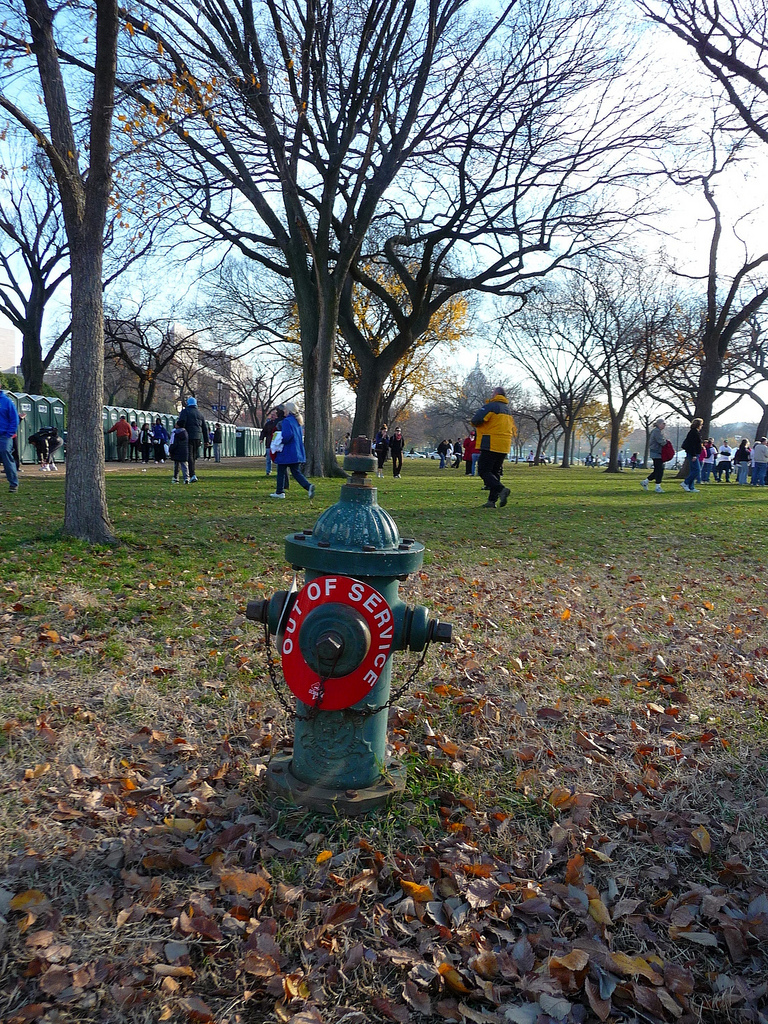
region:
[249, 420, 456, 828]
A fire water post is out of order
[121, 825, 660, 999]
Many red and yellow dry leaves on the grass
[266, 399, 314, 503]
A woman wearing a hat in blue coat is walking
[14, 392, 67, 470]
Three of the temporary mobile toilets.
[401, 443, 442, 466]
Some cars parking in the distance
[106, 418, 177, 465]
A group of people gathering in front of the toilets.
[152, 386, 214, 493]
An adult and a child are walking together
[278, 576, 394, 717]
OUT OF SERVICE sign on hydrant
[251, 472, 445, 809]
fire hydrant in the grass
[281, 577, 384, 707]
OUT OF SERVICE sign is red and round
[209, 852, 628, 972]
leaves are in the grass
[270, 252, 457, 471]
tree has yellow leaves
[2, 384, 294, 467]
row of portapotties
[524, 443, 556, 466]
people sitting on a bench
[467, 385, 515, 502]
man is wearing a yellow jacket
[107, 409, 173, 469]
people using the portapotties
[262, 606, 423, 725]
chain on the fire hydrant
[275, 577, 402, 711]
red sign attached to hydrant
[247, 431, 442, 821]
hydrant on top of grass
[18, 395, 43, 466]
port a potty on concrete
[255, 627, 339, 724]
chain attached to hydrant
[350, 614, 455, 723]
chain attached to hydrant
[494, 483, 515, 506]
shoe on top of foot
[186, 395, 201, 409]
hat on top of head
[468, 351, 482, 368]
steeple on top of building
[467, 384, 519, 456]
man wearing yellow jacket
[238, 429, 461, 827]
fire hydrant in grass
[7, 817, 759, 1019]
leaves in the grass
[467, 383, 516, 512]
a person walking through the grass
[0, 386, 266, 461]
porta pottys in a park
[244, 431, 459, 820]
a green fire hydrant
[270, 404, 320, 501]
a woman walking through the grass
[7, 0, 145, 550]
a tree in the park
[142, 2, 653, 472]
a tree in a park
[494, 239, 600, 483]
a tree in a field of grass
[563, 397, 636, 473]
a tree surounded by people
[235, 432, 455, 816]
green and red fire hydrant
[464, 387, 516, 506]
person in a yellow coat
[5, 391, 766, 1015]
a park full of people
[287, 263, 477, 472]
tree with yellow leaves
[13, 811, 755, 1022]
brown and yellow leaves on the ground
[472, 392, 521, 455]
the jacket is yellow and blue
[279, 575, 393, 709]
the sign say's out of service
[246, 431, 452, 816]
the sign on the fire hydrant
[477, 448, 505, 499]
the pants are black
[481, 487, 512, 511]
the shoes are black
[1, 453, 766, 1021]
the leaves on the ground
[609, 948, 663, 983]
the leaf is yellow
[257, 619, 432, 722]
the chains are black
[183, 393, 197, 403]
the hat is blue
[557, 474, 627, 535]
Large patch of grass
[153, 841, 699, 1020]
Leaves on the ground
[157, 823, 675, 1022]
Leaves across the ground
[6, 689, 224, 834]
Leaves on the ground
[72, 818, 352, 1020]
Leaves across the ground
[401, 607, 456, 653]
Side of a hydrant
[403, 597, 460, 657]
Side of a fire hydrant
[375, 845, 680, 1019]
Leaves on the ground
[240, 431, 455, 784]
a green patina fire hydrant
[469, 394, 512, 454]
a yellow and black jacket